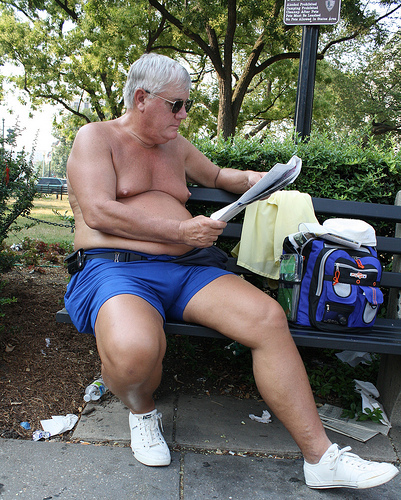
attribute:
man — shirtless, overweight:
[68, 49, 303, 474]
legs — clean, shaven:
[94, 255, 341, 476]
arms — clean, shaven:
[70, 121, 258, 250]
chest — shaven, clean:
[110, 145, 190, 222]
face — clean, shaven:
[139, 102, 190, 146]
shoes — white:
[126, 412, 173, 468]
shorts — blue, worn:
[67, 246, 233, 324]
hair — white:
[126, 52, 190, 99]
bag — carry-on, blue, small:
[280, 232, 383, 334]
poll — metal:
[298, 25, 316, 146]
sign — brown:
[282, 0, 342, 27]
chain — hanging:
[43, 220, 73, 232]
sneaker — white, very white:
[301, 445, 399, 490]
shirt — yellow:
[271, 188, 318, 237]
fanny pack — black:
[124, 247, 233, 267]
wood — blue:
[318, 195, 400, 219]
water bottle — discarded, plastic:
[81, 380, 106, 403]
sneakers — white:
[126, 409, 400, 491]